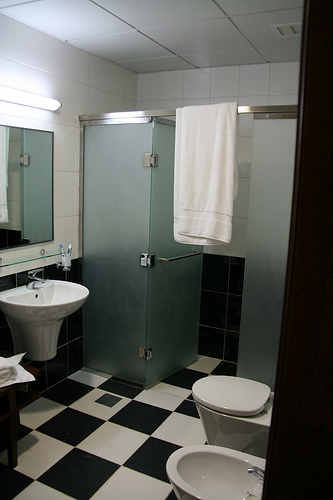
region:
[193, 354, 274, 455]
a white bathroom toilet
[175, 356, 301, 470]
a toilet lid down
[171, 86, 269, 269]
a towel hanging from pole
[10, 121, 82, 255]
mirror on the wall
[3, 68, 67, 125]
light on the wall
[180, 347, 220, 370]
Large white tile on the floor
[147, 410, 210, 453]
Large white tile on the floor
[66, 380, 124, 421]
Large white tile on the floor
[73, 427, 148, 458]
Large white tile on the floor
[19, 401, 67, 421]
Large white tile on the floor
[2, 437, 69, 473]
Large white tile on the floor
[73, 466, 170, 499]
Large white tile on the floor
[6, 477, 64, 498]
Large white tile on the floor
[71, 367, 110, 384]
Large white tile on the floor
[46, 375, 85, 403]
LArge black tile on floor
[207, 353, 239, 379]
LArge black tile on floor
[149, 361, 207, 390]
LArge black tile on floor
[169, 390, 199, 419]
LArge black tile on floor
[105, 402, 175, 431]
LArge black tile on floor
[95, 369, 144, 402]
LArge black tile on floor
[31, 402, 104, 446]
LArge black tile on floor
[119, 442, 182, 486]
LArge black tile on floor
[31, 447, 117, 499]
LArge black tile on floor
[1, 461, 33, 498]
LArge black tile on floor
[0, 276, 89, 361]
the white bathroom sink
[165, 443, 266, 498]
the shiny white bidet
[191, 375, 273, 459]
the shiny white toilet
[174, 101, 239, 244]
the white towel hanging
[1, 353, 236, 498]
the black and white flooring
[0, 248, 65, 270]
the small glass shelf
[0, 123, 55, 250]
the mirror is hanging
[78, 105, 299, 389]
the glass doors to the shower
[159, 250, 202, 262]
the long silver door handle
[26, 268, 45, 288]
the silver water fixture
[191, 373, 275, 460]
white toilet and seat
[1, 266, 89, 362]
white wall mounted sink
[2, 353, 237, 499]
black and white checkered floor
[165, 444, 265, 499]
white porcelain urinal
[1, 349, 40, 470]
towels on top of table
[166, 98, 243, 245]
hanging white bath towel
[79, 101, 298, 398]
shower with foggy doors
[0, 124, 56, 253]
bathroom mirror with metal frame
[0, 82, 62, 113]
bright florescent light strip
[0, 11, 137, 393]
white and black tiled wall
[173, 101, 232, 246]
White towel hanging over shower bar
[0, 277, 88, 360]
White sink attached to a wall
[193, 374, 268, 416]
White cover on a toilet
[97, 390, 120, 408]
Colored square on a tile